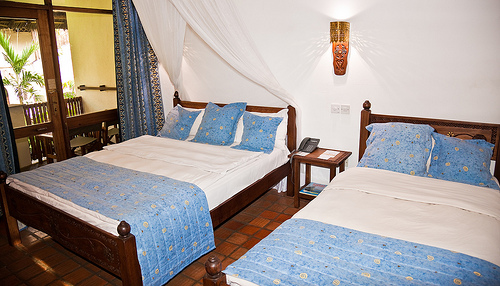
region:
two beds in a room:
[3, 12, 456, 282]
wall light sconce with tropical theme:
[311, 12, 377, 91]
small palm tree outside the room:
[0, 19, 85, 142]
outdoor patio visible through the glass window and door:
[5, 13, 159, 200]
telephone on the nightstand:
[293, 120, 357, 222]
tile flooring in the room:
[5, 105, 257, 282]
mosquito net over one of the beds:
[113, 2, 315, 201]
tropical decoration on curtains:
[88, 7, 191, 165]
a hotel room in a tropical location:
[5, 9, 496, 279]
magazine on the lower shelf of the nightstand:
[298, 172, 339, 206]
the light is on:
[296, 0, 388, 85]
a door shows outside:
[2, 7, 103, 157]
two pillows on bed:
[351, 103, 497, 218]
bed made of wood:
[55, 203, 125, 268]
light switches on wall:
[290, 85, 372, 133]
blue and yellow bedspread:
[281, 223, 316, 263]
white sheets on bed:
[181, 133, 219, 208]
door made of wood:
[16, 6, 111, 156]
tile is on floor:
[17, 250, 53, 280]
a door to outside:
[7, 15, 109, 123]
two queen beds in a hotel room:
[7, 4, 493, 284]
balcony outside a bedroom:
[1, 74, 121, 166]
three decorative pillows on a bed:
[153, 101, 283, 153]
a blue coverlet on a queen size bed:
[7, 155, 217, 282]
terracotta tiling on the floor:
[6, 183, 322, 284]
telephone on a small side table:
[287, 131, 355, 199]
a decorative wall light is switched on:
[326, 15, 352, 78]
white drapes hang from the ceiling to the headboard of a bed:
[131, 1, 301, 151]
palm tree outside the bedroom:
[2, 33, 46, 118]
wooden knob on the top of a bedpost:
[114, 218, 135, 239]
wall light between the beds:
[323, 20, 354, 76]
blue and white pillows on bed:
[152, 100, 282, 150]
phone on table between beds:
[292, 128, 322, 153]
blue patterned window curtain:
[108, 0, 169, 140]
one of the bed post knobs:
[116, 215, 131, 240]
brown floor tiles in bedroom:
[232, 210, 267, 236]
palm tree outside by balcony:
[0, 28, 45, 100]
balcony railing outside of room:
[22, 96, 87, 117]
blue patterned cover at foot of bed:
[22, 151, 210, 251]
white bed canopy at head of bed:
[134, 1, 297, 111]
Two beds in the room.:
[5, 52, 481, 278]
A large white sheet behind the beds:
[136, 1, 498, 145]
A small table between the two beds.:
[287, 128, 345, 206]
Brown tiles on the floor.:
[26, 150, 336, 284]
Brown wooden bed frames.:
[0, 62, 475, 283]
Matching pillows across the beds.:
[111, 87, 495, 196]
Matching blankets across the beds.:
[58, 159, 496, 285]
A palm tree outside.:
[9, 45, 54, 103]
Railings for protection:
[13, 94, 106, 141]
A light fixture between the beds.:
[310, 3, 358, 77]